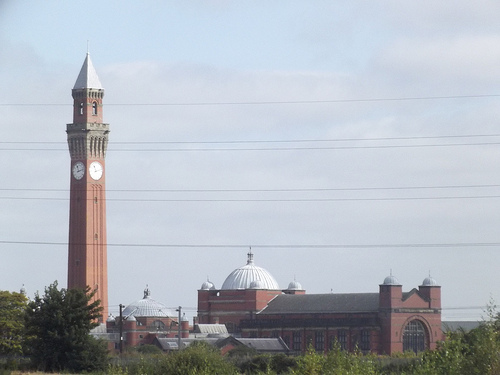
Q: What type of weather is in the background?
A: It is overcast.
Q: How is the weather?
A: It is overcast.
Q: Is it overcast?
A: Yes, it is overcast.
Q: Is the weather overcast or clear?
A: It is overcast.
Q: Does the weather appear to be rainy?
A: No, it is overcast.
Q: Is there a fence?
A: No, there are no fences.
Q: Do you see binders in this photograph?
A: No, there are no binders.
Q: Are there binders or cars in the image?
A: No, there are no binders or cars.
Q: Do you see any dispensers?
A: No, there are no dispensers.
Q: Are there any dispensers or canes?
A: No, there are no dispensers or canes.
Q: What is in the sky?
A: The wires are in the sky.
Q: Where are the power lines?
A: The power lines are in the sky.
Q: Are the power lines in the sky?
A: Yes, the power lines are in the sky.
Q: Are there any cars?
A: No, there are no cars.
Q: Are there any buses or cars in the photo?
A: No, there are no cars or buses.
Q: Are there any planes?
A: No, there are no planes.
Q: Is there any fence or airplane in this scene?
A: No, there are no airplanes or fences.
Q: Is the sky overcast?
A: Yes, the sky is overcast.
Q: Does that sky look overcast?
A: Yes, the sky is overcast.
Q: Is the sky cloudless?
A: No, the sky is overcast.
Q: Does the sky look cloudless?
A: No, the sky is overcast.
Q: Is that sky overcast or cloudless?
A: The sky is overcast.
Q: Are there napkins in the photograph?
A: No, there are no napkins.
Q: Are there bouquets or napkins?
A: No, there are no napkins or bouquets.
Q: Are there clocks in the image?
A: Yes, there is a clock.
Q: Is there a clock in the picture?
A: Yes, there is a clock.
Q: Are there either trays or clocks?
A: Yes, there is a clock.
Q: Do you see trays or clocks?
A: Yes, there is a clock.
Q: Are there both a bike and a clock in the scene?
A: No, there is a clock but no bikes.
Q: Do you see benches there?
A: No, there are no benches.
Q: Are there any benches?
A: No, there are no benches.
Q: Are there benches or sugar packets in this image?
A: No, there are no benches or sugar packets.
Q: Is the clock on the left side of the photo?
A: Yes, the clock is on the left of the image.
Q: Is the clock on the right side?
A: No, the clock is on the left of the image.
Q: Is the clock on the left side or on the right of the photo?
A: The clock is on the left of the image.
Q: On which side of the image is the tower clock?
A: The clock is on the left of the image.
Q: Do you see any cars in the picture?
A: No, there are no cars.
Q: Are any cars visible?
A: No, there are no cars.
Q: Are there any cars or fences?
A: No, there are no cars or fences.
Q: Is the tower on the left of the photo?
A: Yes, the tower is on the left of the image.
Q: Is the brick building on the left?
A: Yes, the tower is on the left of the image.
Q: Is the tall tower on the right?
A: No, the tower is on the left of the image.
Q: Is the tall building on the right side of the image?
A: No, the tower is on the left of the image.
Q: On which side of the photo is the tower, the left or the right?
A: The tower is on the left of the image.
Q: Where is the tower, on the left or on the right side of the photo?
A: The tower is on the left of the image.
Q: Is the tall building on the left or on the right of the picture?
A: The tower is on the left of the image.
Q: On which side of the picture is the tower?
A: The tower is on the left of the image.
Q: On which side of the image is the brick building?
A: The tower is on the left of the image.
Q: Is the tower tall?
A: Yes, the tower is tall.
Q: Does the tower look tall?
A: Yes, the tower is tall.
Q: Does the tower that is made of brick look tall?
A: Yes, the tower is tall.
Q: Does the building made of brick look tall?
A: Yes, the tower is tall.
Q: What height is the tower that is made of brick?
A: The tower is tall.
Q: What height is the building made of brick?
A: The tower is tall.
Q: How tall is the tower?
A: The tower is tall.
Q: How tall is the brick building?
A: The tower is tall.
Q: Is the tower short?
A: No, the tower is tall.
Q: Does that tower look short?
A: No, the tower is tall.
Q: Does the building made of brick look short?
A: No, the tower is tall.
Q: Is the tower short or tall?
A: The tower is tall.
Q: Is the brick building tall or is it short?
A: The tower is tall.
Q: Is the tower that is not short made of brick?
A: Yes, the tower is made of brick.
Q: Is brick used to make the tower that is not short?
A: Yes, the tower is made of brick.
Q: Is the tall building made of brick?
A: Yes, the tower is made of brick.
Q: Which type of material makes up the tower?
A: The tower is made of brick.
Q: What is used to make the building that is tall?
A: The tower is made of brick.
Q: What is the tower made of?
A: The tower is made of brick.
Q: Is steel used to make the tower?
A: No, the tower is made of brick.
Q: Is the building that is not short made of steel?
A: No, the tower is made of brick.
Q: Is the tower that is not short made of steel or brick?
A: The tower is made of brick.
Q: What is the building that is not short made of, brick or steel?
A: The tower is made of brick.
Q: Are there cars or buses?
A: No, there are no cars or buses.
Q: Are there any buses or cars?
A: No, there are no cars or buses.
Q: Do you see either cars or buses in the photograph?
A: No, there are no cars or buses.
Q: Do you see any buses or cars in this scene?
A: No, there are no cars or buses.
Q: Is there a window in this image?
A: Yes, there is a window.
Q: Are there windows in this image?
A: Yes, there is a window.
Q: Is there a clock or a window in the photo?
A: Yes, there is a window.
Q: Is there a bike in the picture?
A: No, there are no bikes.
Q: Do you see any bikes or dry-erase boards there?
A: No, there are no bikes or dry-erase boards.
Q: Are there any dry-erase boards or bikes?
A: No, there are no bikes or dry-erase boards.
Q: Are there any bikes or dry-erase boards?
A: No, there are no bikes or dry-erase boards.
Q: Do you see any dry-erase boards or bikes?
A: No, there are no bikes or dry-erase boards.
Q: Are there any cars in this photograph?
A: No, there are no cars.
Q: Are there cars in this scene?
A: No, there are no cars.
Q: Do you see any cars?
A: No, there are no cars.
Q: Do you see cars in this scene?
A: No, there are no cars.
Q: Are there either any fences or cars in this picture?
A: No, there are no cars or fences.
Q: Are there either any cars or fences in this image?
A: No, there are no cars or fences.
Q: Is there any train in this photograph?
A: No, there are no trains.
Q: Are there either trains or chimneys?
A: No, there are no trains or chimneys.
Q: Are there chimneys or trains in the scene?
A: No, there are no trains or chimneys.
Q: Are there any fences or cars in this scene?
A: No, there are no cars or fences.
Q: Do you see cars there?
A: No, there are no cars.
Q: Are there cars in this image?
A: No, there are no cars.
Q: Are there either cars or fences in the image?
A: No, there are no cars or fences.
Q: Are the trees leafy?
A: Yes, the trees are leafy.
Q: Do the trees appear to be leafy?
A: Yes, the trees are leafy.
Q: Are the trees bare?
A: No, the trees are leafy.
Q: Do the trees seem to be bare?
A: No, the trees are leafy.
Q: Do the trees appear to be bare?
A: No, the trees are leafy.